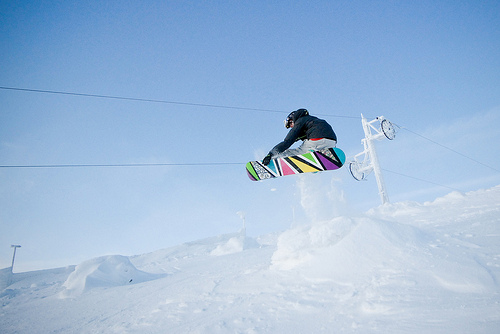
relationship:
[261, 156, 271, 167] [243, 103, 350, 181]
glove being worn by man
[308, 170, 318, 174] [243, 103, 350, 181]
glove being worn by man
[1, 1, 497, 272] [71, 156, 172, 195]
sky not void of cloud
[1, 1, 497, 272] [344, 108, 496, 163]
sky not void of cloud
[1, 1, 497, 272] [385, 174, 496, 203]
sky not void of cloud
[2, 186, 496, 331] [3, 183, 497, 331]
snow on ground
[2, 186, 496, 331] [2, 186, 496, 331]
snow on hill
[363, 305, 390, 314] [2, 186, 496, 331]
track on snow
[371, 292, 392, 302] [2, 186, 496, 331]
track on snow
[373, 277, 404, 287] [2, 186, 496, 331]
track on snow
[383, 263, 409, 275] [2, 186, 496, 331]
track on snow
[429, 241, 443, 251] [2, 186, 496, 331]
track on snow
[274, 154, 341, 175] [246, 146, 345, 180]
rainbow on snowboard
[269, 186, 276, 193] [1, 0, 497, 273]
snow in air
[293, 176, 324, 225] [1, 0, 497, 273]
snow in air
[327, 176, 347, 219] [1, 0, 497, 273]
snow in air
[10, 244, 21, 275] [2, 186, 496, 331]
pole in snow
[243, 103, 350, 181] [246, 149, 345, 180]
man on board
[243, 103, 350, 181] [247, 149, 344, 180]
man on snowboard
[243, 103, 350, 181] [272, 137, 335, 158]
man wearing pants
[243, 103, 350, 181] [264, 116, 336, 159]
man wearing coat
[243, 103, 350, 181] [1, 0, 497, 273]
man in air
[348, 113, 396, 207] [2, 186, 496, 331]
apparatus in snow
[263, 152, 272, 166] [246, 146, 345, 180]
hand on snowboard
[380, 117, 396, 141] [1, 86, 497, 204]
wheel of ski lift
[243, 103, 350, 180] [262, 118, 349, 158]
man wearing jacket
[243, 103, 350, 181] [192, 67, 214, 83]
man in air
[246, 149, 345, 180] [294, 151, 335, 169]
board decorated colors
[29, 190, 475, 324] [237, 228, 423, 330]
mountainside covered snow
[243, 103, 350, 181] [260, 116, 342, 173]
man wearing jacket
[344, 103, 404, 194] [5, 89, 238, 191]
device used lifts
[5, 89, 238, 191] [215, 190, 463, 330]
lifts move up mountain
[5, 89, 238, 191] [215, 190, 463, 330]
lifts down mountain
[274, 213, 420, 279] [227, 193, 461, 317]
snow accumulated mountain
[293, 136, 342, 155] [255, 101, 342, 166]
pants worn man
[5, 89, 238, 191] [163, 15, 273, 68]
lifts hanging air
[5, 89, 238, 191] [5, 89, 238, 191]
lifts used lifts